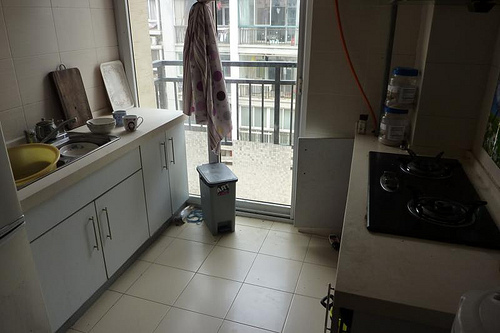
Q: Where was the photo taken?
A: It was taken at the kitchen.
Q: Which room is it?
A: It is a kitchen.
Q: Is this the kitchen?
A: Yes, it is the kitchen.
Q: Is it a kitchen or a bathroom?
A: It is a kitchen.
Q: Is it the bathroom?
A: No, it is the kitchen.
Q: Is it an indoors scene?
A: Yes, it is indoors.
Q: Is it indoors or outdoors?
A: It is indoors.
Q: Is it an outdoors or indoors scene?
A: It is indoors.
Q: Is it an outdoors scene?
A: No, it is indoors.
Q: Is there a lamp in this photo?
A: No, there are no lamps.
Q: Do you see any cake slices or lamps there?
A: No, there are no lamps or cake slices.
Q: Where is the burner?
A: The burner is in the kitchen.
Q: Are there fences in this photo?
A: No, there are no fences.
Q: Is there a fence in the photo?
A: No, there are no fences.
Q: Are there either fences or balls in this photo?
A: No, there are no fences or balls.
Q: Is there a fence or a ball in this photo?
A: No, there are no fences or balls.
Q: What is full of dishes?
A: The sink is full of dishes.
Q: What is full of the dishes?
A: The sink is full of dishes.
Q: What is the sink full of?
A: The sink is full of dishes.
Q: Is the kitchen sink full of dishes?
A: Yes, the sink is full of dishes.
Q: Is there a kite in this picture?
A: No, there are no kites.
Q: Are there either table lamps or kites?
A: No, there are no kites or table lamps.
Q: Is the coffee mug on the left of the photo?
A: Yes, the coffee mug is on the left of the image.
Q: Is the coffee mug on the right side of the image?
A: No, the coffee mug is on the left of the image.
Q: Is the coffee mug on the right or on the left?
A: The coffee mug is on the left of the image.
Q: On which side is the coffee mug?
A: The coffee mug is on the left of the image.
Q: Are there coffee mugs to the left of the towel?
A: Yes, there is a coffee mug to the left of the towel.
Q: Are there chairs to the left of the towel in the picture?
A: No, there is a coffee mug to the left of the towel.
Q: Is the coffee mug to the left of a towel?
A: Yes, the coffee mug is to the left of a towel.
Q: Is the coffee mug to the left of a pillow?
A: No, the coffee mug is to the left of a towel.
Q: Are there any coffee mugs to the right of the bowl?
A: Yes, there is a coffee mug to the right of the bowl.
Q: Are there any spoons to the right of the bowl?
A: No, there is a coffee mug to the right of the bowl.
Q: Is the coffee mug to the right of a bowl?
A: Yes, the coffee mug is to the right of a bowl.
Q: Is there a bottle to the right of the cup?
A: No, there is a coffee mug to the right of the cup.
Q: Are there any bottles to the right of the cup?
A: No, there is a coffee mug to the right of the cup.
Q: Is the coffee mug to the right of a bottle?
A: No, the coffee mug is to the right of the cup.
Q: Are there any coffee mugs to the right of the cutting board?
A: Yes, there is a coffee mug to the right of the cutting board.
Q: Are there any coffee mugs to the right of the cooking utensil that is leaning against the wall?
A: Yes, there is a coffee mug to the right of the cutting board.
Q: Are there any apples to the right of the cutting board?
A: No, there is a coffee mug to the right of the cutting board.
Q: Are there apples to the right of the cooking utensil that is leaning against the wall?
A: No, there is a coffee mug to the right of the cutting board.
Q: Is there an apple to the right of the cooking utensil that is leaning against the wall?
A: No, there is a coffee mug to the right of the cutting board.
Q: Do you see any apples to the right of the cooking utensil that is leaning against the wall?
A: No, there is a coffee mug to the right of the cutting board.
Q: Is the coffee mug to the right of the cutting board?
A: Yes, the coffee mug is to the right of the cutting board.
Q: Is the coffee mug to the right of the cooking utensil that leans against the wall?
A: Yes, the coffee mug is to the right of the cutting board.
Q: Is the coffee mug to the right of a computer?
A: No, the coffee mug is to the right of the cutting board.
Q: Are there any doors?
A: Yes, there is a door.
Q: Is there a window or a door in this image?
A: Yes, there is a door.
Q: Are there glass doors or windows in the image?
A: Yes, there is a glass door.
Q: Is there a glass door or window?
A: Yes, there is a glass door.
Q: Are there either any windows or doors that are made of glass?
A: Yes, the door is made of glass.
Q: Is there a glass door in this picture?
A: Yes, there is a door that is made of glass.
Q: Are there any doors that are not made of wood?
A: Yes, there is a door that is made of glass.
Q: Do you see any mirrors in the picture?
A: No, there are no mirrors.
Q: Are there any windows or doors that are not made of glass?
A: No, there is a door but it is made of glass.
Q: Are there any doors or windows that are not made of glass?
A: No, there is a door but it is made of glass.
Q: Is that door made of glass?
A: Yes, the door is made of glass.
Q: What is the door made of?
A: The door is made of glass.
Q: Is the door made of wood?
A: No, the door is made of glass.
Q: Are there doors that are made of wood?
A: No, there is a door but it is made of glass.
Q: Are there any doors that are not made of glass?
A: No, there is a door but it is made of glass.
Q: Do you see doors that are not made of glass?
A: No, there is a door but it is made of glass.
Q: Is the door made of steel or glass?
A: The door is made of glass.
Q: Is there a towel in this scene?
A: Yes, there is a towel.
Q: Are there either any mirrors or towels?
A: Yes, there is a towel.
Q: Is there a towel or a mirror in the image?
A: Yes, there is a towel.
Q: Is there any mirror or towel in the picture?
A: Yes, there is a towel.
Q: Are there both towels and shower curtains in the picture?
A: No, there is a towel but no shower curtains.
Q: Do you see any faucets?
A: No, there are no faucets.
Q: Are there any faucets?
A: No, there are no faucets.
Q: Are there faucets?
A: No, there are no faucets.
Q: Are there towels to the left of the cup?
A: No, the towel is to the right of the cup.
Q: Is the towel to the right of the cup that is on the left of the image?
A: Yes, the towel is to the right of the cup.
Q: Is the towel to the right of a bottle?
A: No, the towel is to the right of the cup.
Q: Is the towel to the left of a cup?
A: No, the towel is to the right of a cup.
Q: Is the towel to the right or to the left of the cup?
A: The towel is to the right of the cup.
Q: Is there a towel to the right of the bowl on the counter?
A: Yes, there is a towel to the right of the bowl.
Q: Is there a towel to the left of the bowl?
A: No, the towel is to the right of the bowl.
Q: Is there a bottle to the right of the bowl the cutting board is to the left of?
A: No, there is a towel to the right of the bowl.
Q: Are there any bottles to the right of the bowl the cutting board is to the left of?
A: No, there is a towel to the right of the bowl.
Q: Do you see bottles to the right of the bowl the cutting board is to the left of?
A: No, there is a towel to the right of the bowl.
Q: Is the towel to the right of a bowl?
A: Yes, the towel is to the right of a bowl.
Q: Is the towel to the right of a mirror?
A: No, the towel is to the right of a bowl.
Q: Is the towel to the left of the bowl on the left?
A: No, the towel is to the right of the bowl.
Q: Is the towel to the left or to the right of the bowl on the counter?
A: The towel is to the right of the bowl.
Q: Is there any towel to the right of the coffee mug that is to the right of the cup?
A: Yes, there is a towel to the right of the coffee mug.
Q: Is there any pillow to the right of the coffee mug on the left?
A: No, there is a towel to the right of the coffee mug.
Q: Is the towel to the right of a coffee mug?
A: Yes, the towel is to the right of a coffee mug.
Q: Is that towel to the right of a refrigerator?
A: No, the towel is to the right of a coffee mug.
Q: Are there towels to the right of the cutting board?
A: Yes, there is a towel to the right of the cutting board.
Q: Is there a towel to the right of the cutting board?
A: Yes, there is a towel to the right of the cutting board.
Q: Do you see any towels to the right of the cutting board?
A: Yes, there is a towel to the right of the cutting board.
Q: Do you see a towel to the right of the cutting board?
A: Yes, there is a towel to the right of the cutting board.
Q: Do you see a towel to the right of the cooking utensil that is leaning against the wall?
A: Yes, there is a towel to the right of the cutting board.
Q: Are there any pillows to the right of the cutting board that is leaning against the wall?
A: No, there is a towel to the right of the cutting board.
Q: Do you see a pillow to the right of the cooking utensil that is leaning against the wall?
A: No, there is a towel to the right of the cutting board.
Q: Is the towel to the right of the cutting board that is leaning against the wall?
A: Yes, the towel is to the right of the cutting board.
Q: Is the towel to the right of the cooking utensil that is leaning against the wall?
A: Yes, the towel is to the right of the cutting board.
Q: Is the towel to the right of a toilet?
A: No, the towel is to the right of the cutting board.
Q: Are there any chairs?
A: No, there are no chairs.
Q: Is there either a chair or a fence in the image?
A: No, there are no chairs or fences.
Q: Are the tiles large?
A: Yes, the tiles are large.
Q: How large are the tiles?
A: The tiles are large.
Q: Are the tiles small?
A: No, the tiles are large.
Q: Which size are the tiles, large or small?
A: The tiles are large.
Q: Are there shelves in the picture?
A: No, there are no shelves.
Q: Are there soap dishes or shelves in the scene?
A: No, there are no shelves or soap dishes.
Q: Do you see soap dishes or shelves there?
A: No, there are no shelves or soap dishes.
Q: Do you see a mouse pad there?
A: No, there are no mouse pads.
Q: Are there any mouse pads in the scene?
A: No, there are no mouse pads.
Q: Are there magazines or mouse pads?
A: No, there are no mouse pads or magazines.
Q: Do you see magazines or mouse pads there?
A: No, there are no mouse pads or magazines.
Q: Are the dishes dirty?
A: Yes, the dishes are dirty.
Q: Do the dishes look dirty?
A: Yes, the dishes are dirty.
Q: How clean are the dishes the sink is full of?
A: The dishes are dirty.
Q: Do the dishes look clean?
A: No, the dishes are dirty.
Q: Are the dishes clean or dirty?
A: The dishes are dirty.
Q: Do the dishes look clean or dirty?
A: The dishes are dirty.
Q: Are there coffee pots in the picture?
A: No, there are no coffee pots.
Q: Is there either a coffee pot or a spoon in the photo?
A: No, there are no coffee pots or spoons.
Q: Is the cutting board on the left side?
A: Yes, the cutting board is on the left of the image.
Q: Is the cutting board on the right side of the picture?
A: No, the cutting board is on the left of the image.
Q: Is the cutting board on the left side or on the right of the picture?
A: The cutting board is on the left of the image.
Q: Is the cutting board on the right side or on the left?
A: The cutting board is on the left of the image.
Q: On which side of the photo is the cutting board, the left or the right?
A: The cutting board is on the left of the image.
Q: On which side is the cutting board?
A: The cutting board is on the left of the image.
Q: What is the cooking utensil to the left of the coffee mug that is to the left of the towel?
A: The cooking utensil is a cutting board.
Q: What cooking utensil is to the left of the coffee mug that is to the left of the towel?
A: The cooking utensil is a cutting board.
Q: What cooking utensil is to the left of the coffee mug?
A: The cooking utensil is a cutting board.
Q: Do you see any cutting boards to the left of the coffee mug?
A: Yes, there is a cutting board to the left of the coffee mug.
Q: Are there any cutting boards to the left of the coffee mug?
A: Yes, there is a cutting board to the left of the coffee mug.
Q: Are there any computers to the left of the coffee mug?
A: No, there is a cutting board to the left of the coffee mug.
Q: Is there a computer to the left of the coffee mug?
A: No, there is a cutting board to the left of the coffee mug.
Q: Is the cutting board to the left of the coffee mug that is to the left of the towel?
A: Yes, the cutting board is to the left of the coffee mug.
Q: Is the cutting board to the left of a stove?
A: No, the cutting board is to the left of the coffee mug.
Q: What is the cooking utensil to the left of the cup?
A: The cooking utensil is a cutting board.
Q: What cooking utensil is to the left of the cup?
A: The cooking utensil is a cutting board.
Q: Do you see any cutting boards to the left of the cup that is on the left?
A: Yes, there is a cutting board to the left of the cup.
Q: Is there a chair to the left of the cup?
A: No, there is a cutting board to the left of the cup.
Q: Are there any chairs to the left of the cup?
A: No, there is a cutting board to the left of the cup.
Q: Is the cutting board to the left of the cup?
A: Yes, the cutting board is to the left of the cup.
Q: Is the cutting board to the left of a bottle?
A: No, the cutting board is to the left of the cup.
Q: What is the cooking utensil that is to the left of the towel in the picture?
A: The cooking utensil is a cutting board.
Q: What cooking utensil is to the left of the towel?
A: The cooking utensil is a cutting board.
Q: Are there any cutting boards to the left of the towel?
A: Yes, there is a cutting board to the left of the towel.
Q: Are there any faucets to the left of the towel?
A: No, there is a cutting board to the left of the towel.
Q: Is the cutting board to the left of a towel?
A: Yes, the cutting board is to the left of a towel.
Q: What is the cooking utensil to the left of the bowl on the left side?
A: The cooking utensil is a cutting board.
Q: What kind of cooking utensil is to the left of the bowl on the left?
A: The cooking utensil is a cutting board.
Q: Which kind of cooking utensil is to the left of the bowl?
A: The cooking utensil is a cutting board.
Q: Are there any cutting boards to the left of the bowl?
A: Yes, there is a cutting board to the left of the bowl.